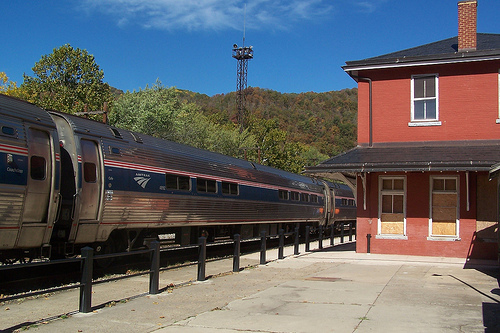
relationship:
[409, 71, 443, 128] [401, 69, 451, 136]
window with frame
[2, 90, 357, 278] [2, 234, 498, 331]
train at station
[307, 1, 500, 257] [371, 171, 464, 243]
building has windows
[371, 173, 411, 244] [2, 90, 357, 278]
window closest to train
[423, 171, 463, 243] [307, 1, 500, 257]
window bottom of building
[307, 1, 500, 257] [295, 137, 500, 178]
building has lower roof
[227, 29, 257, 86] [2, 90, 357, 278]
tower beyond train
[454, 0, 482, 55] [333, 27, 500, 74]
chimney on a roof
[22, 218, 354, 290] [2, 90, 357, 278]
fence next to train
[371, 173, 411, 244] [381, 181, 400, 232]
window boarded up with wood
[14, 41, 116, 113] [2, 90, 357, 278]
tree behind train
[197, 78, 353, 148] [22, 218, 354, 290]
hillside next to tracks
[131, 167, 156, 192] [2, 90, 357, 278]
logo on side train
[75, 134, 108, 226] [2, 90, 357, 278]
door of train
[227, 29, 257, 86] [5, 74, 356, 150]
tower in woods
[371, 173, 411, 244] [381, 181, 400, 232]
window boarded  with plywood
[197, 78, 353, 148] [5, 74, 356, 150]
mountainside has foliage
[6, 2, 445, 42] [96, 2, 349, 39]
sky with white clouds